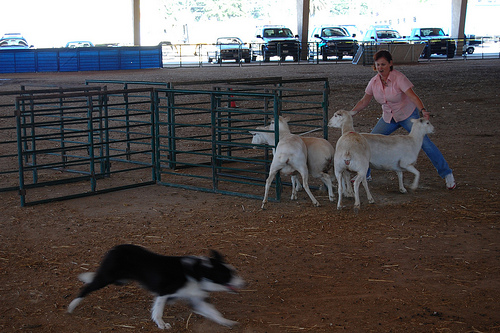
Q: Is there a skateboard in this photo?
A: No, there are no skateboards.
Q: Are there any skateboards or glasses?
A: No, there are no skateboards or glasses.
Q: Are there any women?
A: Yes, there is a woman.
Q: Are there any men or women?
A: Yes, there is a woman.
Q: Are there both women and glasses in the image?
A: No, there is a woman but no glasses.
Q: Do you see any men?
A: No, there are no men.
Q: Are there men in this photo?
A: No, there are no men.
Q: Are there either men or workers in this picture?
A: No, there are no men or workers.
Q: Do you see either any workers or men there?
A: No, there are no men or workers.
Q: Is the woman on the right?
A: Yes, the woman is on the right of the image.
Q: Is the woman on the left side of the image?
A: No, the woman is on the right of the image.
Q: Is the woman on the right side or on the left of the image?
A: The woman is on the right of the image.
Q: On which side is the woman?
A: The woman is on the right of the image.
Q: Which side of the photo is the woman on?
A: The woman is on the right of the image.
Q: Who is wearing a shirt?
A: The woman is wearing a shirt.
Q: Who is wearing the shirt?
A: The woman is wearing a shirt.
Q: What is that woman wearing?
A: The woman is wearing a shirt.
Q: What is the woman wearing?
A: The woman is wearing a shirt.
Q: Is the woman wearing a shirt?
A: Yes, the woman is wearing a shirt.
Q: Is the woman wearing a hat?
A: No, the woman is wearing a shirt.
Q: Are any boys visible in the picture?
A: No, there are no boys.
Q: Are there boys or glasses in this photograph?
A: No, there are no boys or glasses.